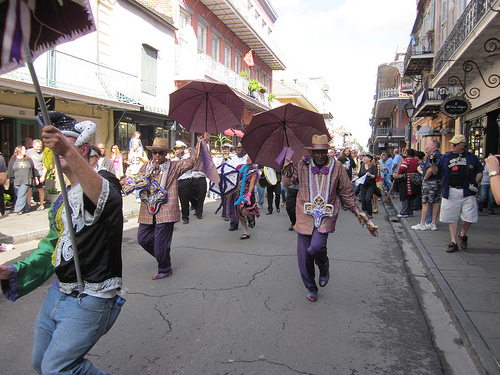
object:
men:
[278, 133, 381, 300]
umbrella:
[240, 103, 331, 171]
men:
[167, 140, 207, 223]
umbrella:
[166, 79, 247, 136]